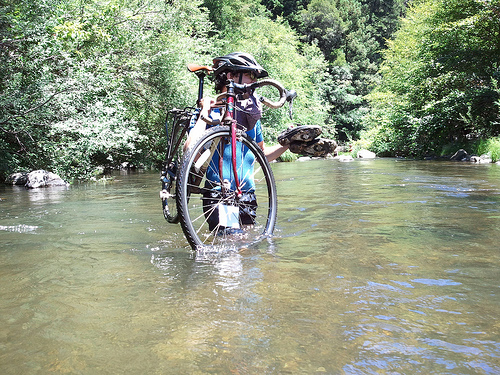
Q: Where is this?
A: This is at the river.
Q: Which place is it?
A: It is a river.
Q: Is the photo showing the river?
A: Yes, it is showing the river.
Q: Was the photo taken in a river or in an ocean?
A: It was taken at a river.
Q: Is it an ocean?
A: No, it is a river.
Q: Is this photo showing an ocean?
A: No, the picture is showing a river.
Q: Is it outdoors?
A: Yes, it is outdoors.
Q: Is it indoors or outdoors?
A: It is outdoors.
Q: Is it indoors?
A: No, it is outdoors.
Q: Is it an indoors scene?
A: No, it is outdoors.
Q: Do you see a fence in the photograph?
A: No, there are no fences.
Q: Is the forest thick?
A: Yes, the forest is thick.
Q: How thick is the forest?
A: The forest is thick.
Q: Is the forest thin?
A: No, the forest is thick.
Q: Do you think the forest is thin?
A: No, the forest is thick.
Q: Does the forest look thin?
A: No, the forest is thick.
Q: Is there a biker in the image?
A: Yes, there is a biker.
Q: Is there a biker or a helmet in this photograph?
A: Yes, there is a biker.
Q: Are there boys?
A: No, there are no boys.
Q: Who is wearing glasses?
A: The motorcyclist is wearing glasses.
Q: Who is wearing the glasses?
A: The motorcyclist is wearing glasses.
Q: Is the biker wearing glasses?
A: Yes, the biker is wearing glasses.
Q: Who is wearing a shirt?
A: The biker is wearing a shirt.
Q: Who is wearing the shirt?
A: The biker is wearing a shirt.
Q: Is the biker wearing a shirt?
A: Yes, the biker is wearing a shirt.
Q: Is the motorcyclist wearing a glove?
A: No, the motorcyclist is wearing a shirt.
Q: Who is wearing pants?
A: The motorcyclist is wearing pants.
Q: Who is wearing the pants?
A: The motorcyclist is wearing pants.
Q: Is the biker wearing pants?
A: Yes, the biker is wearing pants.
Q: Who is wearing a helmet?
A: The motorcyclist is wearing a helmet.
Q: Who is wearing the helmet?
A: The motorcyclist is wearing a helmet.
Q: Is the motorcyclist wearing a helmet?
A: Yes, the motorcyclist is wearing a helmet.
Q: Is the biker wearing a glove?
A: No, the biker is wearing a helmet.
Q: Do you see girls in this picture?
A: No, there are no girls.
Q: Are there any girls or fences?
A: No, there are no girls or fences.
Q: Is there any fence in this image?
A: No, there are no fences.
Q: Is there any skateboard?
A: No, there are no skateboards.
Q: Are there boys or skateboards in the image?
A: No, there are no skateboards or boys.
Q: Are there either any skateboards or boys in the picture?
A: No, there are no skateboards or boys.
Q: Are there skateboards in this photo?
A: No, there are no skateboards.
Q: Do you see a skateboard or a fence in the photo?
A: No, there are no skateboards or fences.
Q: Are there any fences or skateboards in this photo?
A: No, there are no skateboards or fences.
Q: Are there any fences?
A: No, there are no fences.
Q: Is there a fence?
A: No, there are no fences.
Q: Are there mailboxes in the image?
A: No, there are no mailboxes.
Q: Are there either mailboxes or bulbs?
A: No, there are no mailboxes or bulbs.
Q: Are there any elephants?
A: No, there are no elephants.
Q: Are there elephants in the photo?
A: No, there are no elephants.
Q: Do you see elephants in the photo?
A: No, there are no elephants.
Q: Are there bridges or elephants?
A: No, there are no elephants or bridges.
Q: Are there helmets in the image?
A: Yes, there is a helmet.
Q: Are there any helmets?
A: Yes, there is a helmet.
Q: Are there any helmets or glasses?
A: Yes, there is a helmet.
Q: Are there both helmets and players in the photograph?
A: No, there is a helmet but no players.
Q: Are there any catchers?
A: No, there are no catchers.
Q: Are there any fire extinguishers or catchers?
A: No, there are no catchers or fire extinguishers.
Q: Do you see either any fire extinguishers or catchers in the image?
A: No, there are no catchers or fire extinguishers.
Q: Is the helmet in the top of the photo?
A: Yes, the helmet is in the top of the image.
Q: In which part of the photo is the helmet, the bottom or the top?
A: The helmet is in the top of the image.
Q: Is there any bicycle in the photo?
A: Yes, there is a bicycle.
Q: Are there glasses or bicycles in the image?
A: Yes, there is a bicycle.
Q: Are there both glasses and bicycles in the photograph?
A: Yes, there are both a bicycle and glasses.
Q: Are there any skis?
A: No, there are no skis.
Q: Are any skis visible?
A: No, there are no skis.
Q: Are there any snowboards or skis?
A: No, there are no skis or snowboards.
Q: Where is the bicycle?
A: The bicycle is in the river.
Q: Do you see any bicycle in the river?
A: Yes, there is a bicycle in the river.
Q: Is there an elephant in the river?
A: No, there is a bicycle in the river.